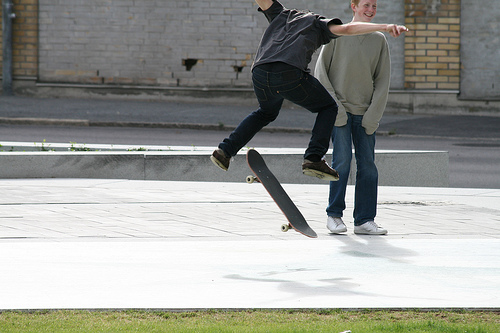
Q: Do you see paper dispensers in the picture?
A: No, there are no paper dispensers.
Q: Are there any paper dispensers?
A: No, there are no paper dispensers.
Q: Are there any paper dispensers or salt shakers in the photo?
A: No, there are no paper dispensers or salt shakers.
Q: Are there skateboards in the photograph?
A: Yes, there is a skateboard.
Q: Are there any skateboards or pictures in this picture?
A: Yes, there is a skateboard.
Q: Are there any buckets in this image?
A: No, there are no buckets.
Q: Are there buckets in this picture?
A: No, there are no buckets.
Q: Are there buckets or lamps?
A: No, there are no buckets or lamps.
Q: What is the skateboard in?
A: The skateboard is in the air.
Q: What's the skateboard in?
A: The skateboard is in the air.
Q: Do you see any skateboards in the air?
A: Yes, there is a skateboard in the air.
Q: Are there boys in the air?
A: No, there is a skateboard in the air.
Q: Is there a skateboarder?
A: Yes, there is a skateboarder.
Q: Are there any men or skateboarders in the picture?
A: Yes, there is a skateboarder.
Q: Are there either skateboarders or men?
A: Yes, there is a skateboarder.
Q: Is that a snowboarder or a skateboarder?
A: That is a skateboarder.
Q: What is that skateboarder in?
A: The skateboarder is in the air.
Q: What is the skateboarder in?
A: The skateboarder is in the air.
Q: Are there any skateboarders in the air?
A: Yes, there is a skateboarder in the air.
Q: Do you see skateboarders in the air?
A: Yes, there is a skateboarder in the air.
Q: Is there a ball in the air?
A: No, there is a skateboarder in the air.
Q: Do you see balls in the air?
A: No, there is a skateboarder in the air.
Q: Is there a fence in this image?
A: No, there are no fences.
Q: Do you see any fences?
A: No, there are no fences.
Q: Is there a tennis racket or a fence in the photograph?
A: No, there are no fences or rackets.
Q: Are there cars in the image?
A: No, there are no cars.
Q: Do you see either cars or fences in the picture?
A: No, there are no cars or fences.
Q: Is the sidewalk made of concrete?
A: Yes, the sidewalk is made of concrete.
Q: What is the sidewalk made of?
A: The sidewalk is made of concrete.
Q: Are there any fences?
A: No, there are no fences.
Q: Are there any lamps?
A: No, there are no lamps.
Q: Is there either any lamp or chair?
A: No, there are no lamps or chairs.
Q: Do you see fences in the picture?
A: No, there are no fences.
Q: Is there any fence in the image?
A: No, there are no fences.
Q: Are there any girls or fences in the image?
A: No, there are no fences or girls.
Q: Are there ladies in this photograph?
A: No, there are no ladies.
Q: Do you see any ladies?
A: No, there are no ladies.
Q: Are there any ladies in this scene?
A: No, there are no ladies.